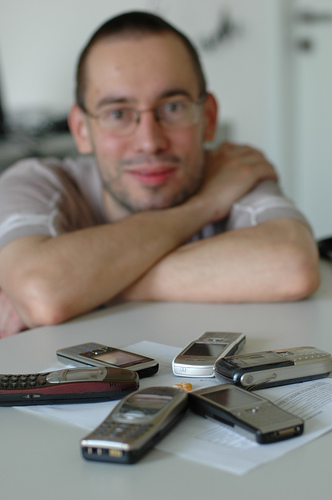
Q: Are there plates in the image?
A: No, there are no plates.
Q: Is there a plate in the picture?
A: No, there are no plates.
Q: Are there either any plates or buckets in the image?
A: No, there are no plates or buckets.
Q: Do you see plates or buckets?
A: No, there are no plates or buckets.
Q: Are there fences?
A: No, there are no fences.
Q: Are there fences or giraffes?
A: No, there are no fences or giraffes.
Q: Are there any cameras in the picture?
A: Yes, there is a camera.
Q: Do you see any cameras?
A: Yes, there is a camera.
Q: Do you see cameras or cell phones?
A: Yes, there is a camera.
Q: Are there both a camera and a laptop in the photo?
A: No, there is a camera but no laptops.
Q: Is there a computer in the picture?
A: No, there are no computers.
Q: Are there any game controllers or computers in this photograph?
A: No, there are no computers or game controllers.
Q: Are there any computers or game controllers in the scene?
A: No, there are no computers or game controllers.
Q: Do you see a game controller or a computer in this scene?
A: No, there are no computers or game controllers.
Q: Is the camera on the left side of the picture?
A: Yes, the camera is on the left of the image.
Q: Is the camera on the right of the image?
A: No, the camera is on the left of the image.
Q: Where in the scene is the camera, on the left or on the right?
A: The camera is on the left of the image.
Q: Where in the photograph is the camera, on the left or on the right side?
A: The camera is on the left of the image.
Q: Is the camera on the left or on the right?
A: The camera is on the left of the image.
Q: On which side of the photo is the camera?
A: The camera is on the left of the image.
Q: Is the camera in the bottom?
A: Yes, the camera is in the bottom of the image.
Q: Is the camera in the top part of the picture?
A: No, the camera is in the bottom of the image.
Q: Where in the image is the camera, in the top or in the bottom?
A: The camera is in the bottom of the image.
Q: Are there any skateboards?
A: No, there are no skateboards.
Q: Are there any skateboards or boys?
A: No, there are no skateboards or boys.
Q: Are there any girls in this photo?
A: No, there are no girls.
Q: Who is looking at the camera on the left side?
A: The man is looking at the camera.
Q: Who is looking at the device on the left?
A: The man is looking at the camera.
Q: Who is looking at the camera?
A: The man is looking at the camera.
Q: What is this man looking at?
A: The man is looking at the camera.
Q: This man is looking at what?
A: The man is looking at the camera.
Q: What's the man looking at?
A: The man is looking at the camera.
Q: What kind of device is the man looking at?
A: The man is looking at the camera.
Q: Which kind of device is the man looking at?
A: The man is looking at the camera.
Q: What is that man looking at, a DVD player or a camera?
A: The man is looking at a camera.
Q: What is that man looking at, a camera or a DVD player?
A: The man is looking at a camera.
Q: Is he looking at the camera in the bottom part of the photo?
A: Yes, the man is looking at the camera.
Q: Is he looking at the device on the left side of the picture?
A: Yes, the man is looking at the camera.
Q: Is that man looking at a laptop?
A: No, the man is looking at the camera.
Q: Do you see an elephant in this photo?
A: No, there are no elephants.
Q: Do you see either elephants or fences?
A: No, there are no elephants or fences.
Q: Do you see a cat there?
A: No, there are no cats.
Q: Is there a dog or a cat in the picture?
A: No, there are no cats or dogs.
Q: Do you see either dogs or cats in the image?
A: No, there are no cats or dogs.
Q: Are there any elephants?
A: No, there are no elephants.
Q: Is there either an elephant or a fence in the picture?
A: No, there are no elephants or fences.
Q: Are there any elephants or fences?
A: No, there are no elephants or fences.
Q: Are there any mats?
A: No, there are no mats.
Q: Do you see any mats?
A: No, there are no mats.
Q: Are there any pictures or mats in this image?
A: No, there are no mats or pictures.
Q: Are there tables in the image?
A: Yes, there is a table.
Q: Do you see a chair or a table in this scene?
A: Yes, there is a table.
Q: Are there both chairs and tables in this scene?
A: No, there is a table but no chairs.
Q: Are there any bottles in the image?
A: No, there are no bottles.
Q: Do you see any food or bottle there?
A: No, there are no bottles or food.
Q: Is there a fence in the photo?
A: No, there are no fences.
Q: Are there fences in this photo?
A: No, there are no fences.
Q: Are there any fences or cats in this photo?
A: No, there are no fences or cats.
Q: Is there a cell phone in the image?
A: Yes, there is a cell phone.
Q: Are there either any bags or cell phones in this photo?
A: Yes, there is a cell phone.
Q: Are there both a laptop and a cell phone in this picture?
A: No, there is a cell phone but no laptops.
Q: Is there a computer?
A: No, there are no computers.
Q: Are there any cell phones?
A: Yes, there is a cell phone.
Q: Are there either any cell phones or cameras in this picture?
A: Yes, there is a cell phone.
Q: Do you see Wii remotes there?
A: No, there are no Wii remotes.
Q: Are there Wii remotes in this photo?
A: No, there are no Wii remotes.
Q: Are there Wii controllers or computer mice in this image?
A: No, there are no Wii controllers or computer mice.